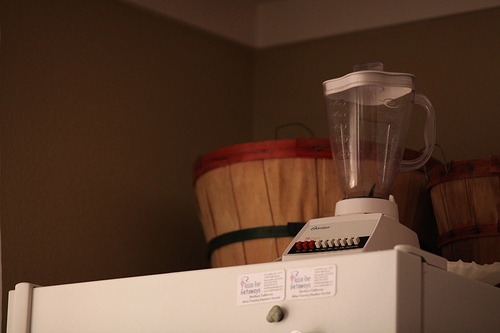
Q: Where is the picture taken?
A: A kitchen.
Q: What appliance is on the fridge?
A: A blender.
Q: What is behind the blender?
A: A basket.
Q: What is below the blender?
A: A fridge.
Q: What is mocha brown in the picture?
A: The walls.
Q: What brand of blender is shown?
A: Oyster.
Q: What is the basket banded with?
A: Red and green.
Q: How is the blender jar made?
A: Of glass.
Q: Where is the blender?
A: On top of the refrigerator.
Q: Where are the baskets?
A: Behind the blender.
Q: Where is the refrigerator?
A: Under the blender and baskets.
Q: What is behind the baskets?
A: Wall.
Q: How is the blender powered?
A: Electric motor.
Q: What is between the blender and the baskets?
A: Coffee filters.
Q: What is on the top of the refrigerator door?
A: Two identical cards.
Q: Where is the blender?
A: On top of the fridge.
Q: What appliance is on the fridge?
A: Blender.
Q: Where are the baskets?
A: On top of the fridge.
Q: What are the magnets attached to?
A: The fridge.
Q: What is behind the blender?
A: Baskets.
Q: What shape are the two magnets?
A: Rectangle.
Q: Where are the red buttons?
A: On the blender.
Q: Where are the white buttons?
A: On the blender.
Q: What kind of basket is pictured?
A: Paper.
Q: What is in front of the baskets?
A: A blender.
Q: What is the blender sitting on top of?
A: Refrigerator.